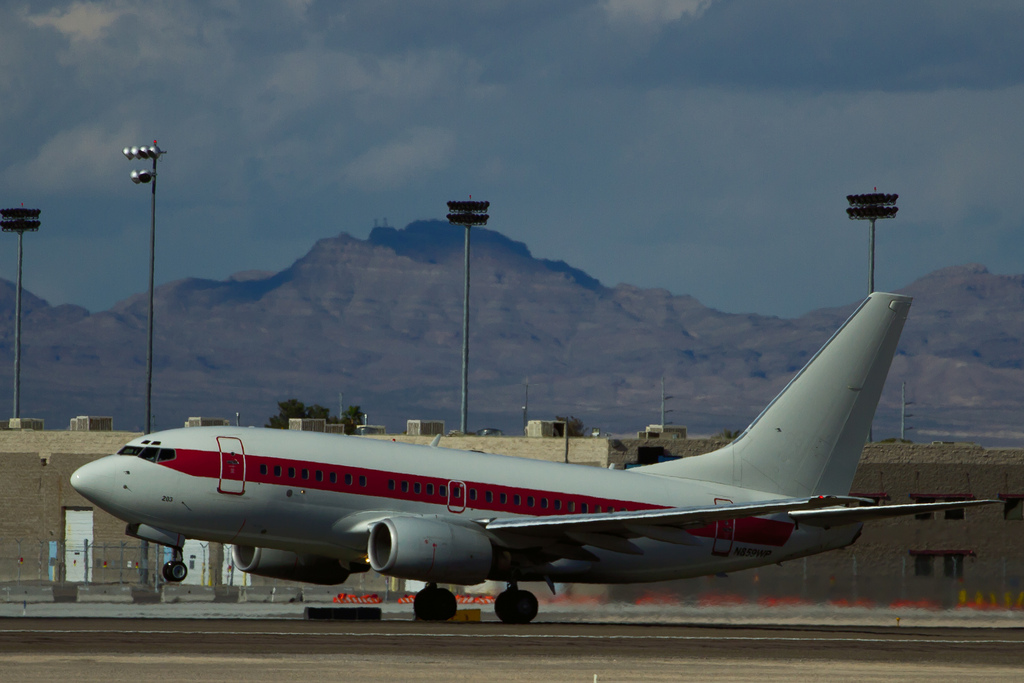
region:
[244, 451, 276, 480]
window on the plane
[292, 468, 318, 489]
window on the plane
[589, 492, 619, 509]
window on the plane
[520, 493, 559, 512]
window on the plane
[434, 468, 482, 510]
window on the plane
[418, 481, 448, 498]
window on the plane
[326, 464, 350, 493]
window on the plane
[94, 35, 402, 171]
puffy clouds in sky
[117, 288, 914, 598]
red and white plane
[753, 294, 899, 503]
white tail on plane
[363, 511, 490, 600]
grey engine on plane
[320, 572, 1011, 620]
orange cones in distance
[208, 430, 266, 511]
red and white door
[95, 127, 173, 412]
silver lights on pole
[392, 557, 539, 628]
wheels are under plane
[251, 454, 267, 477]
window on white airplane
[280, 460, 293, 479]
window on white airplane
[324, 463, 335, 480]
window on white airplane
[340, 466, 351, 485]
window on white airplane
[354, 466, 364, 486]
window on white airplane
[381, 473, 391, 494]
window on white airplane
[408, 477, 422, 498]
window on white airplane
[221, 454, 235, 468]
The window of a plane on a door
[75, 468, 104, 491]
The white nose of a plane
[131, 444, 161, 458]
The windows in the cockpit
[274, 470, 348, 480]
The passenger windows of a plane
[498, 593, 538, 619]
The rear wheels of plane on the ground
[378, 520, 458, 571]
The left engine of a plane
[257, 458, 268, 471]
plane has a window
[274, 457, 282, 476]
plane has a window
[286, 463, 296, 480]
plane has a window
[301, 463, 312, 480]
plane has a window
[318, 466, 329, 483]
plane has a window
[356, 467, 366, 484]
plane has a window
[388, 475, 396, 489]
plane has a window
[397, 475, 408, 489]
plane has a window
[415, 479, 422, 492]
plane has a window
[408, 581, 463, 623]
Tires of a plane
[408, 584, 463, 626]
Tires of a large plane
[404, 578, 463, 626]
Tires of a white plane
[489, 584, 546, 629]
Tires of a plane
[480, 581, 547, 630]
Tires of a large plane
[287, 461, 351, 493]
Windows on a plane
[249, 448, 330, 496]
Windows on a large plane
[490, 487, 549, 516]
Windows on a plane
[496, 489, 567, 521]
Windows on a large plane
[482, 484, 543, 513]
Windows on a white plane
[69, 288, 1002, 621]
white airplane with a red stripe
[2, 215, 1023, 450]
mountain range with patches of vegetation